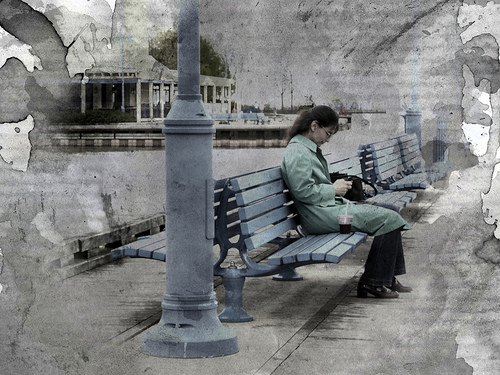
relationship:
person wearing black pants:
[256, 86, 456, 295] [360, 227, 406, 288]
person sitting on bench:
[281, 104, 412, 300] [114, 165, 378, 325]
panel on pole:
[199, 171, 221, 263] [143, 8, 223, 326]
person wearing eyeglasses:
[281, 104, 412, 300] [315, 123, 337, 145]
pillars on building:
[49, 74, 166, 111] [68, 31, 359, 242]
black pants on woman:
[362, 223, 410, 303] [277, 100, 417, 312]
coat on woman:
[279, 132, 412, 236] [242, 73, 418, 307]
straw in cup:
[349, 173, 356, 185] [346, 174, 361, 200]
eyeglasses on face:
[319, 123, 334, 139] [303, 97, 339, 151]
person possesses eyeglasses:
[281, 104, 412, 300] [319, 123, 334, 139]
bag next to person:
[328, 171, 378, 203] [281, 104, 412, 300]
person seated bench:
[281, 104, 412, 300] [214, 131, 437, 319]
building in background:
[70, 63, 247, 124] [27, 27, 492, 234]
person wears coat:
[281, 104, 412, 300] [284, 148, 366, 239]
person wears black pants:
[281, 104, 412, 300] [363, 227, 408, 297]